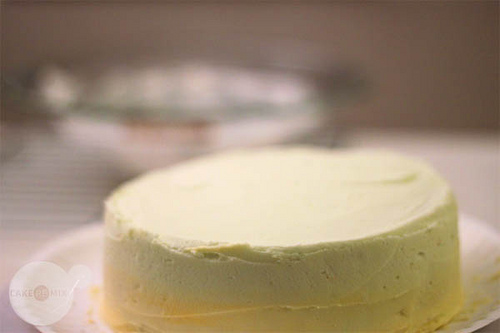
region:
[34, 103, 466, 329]
cake on a plate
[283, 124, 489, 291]
cake on a plate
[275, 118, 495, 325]
cake on a plate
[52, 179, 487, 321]
cake on a plate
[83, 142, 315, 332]
cake on a plate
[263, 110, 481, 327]
cake on a plate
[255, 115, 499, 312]
cake on a plate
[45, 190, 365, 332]
cake on a plate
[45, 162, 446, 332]
a piece of dessert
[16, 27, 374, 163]
blurred picture of the bowl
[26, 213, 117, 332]
the dessert is placed at white plate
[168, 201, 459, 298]
the color of the dessert is yellow green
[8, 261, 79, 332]
the label of the cake and mix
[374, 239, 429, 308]
small holes of the dessert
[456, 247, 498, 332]
pieces scattered at the side of the plate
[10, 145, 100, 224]
stripes mat at the table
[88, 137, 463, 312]
a single piece of dessert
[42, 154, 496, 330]
cake on a plate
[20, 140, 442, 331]
cake on a plate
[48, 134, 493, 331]
cake on a plate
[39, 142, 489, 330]
cake on a plate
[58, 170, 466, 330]
cake on a plate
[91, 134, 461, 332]
cake on a plate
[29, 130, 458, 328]
cake on a plate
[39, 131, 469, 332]
cake on a plate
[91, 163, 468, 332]
cake on a plate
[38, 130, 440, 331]
cake on a plate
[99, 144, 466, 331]
a cake is on a plate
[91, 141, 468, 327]
the cake has one layer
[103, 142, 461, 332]
the cake is frosted with butter cream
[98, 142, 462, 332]
the shape of the dessert is round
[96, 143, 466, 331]
the small cake has been hand frosted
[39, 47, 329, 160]
a blurred object is behind the dessert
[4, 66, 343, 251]
the grate is for cooling the baked goods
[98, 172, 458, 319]
a vanilla cheesecake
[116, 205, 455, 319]
cheesecake is round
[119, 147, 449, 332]
a yellow cake with frosting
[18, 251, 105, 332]
a logo for the company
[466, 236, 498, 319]
pastry on a white dish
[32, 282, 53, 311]
number in middle of logo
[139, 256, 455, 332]
edges are smooth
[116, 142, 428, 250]
plain on the top of cake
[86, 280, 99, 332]
crumbs from the cake on the plate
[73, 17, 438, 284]
this is a cake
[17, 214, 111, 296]
the plate is white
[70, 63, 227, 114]
the background is blurry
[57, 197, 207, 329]
a plate with food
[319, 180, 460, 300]
a plate with food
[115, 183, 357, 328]
a plate with food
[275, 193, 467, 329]
a plate with food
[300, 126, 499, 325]
a plate with food